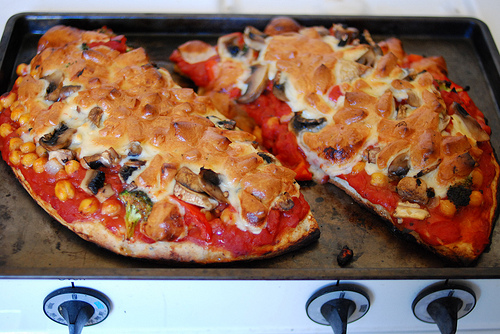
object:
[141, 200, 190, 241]
mushroom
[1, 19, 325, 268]
pizza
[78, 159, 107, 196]
mushroom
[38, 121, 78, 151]
mushroom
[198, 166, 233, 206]
mushroom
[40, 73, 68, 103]
mushroom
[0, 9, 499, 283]
pan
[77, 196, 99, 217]
corn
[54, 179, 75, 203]
corn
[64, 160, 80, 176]
corn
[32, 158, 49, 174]
corn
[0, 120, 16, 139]
corn